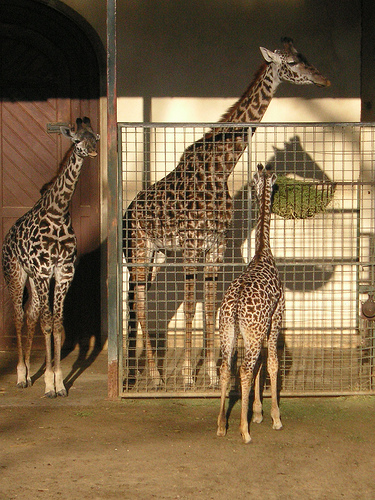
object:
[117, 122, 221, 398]
fence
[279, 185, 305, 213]
hay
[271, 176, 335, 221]
bucket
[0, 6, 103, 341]
door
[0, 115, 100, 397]
giraffe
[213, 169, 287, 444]
giraffe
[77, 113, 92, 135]
horns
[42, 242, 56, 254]
spot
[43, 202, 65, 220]
spot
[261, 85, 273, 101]
spot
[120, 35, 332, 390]
giraffe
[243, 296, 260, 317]
spot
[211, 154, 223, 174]
spot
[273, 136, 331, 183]
shadow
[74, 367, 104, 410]
floor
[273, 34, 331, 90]
head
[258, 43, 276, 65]
ear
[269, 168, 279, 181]
ear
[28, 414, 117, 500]
dirt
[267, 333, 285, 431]
leg